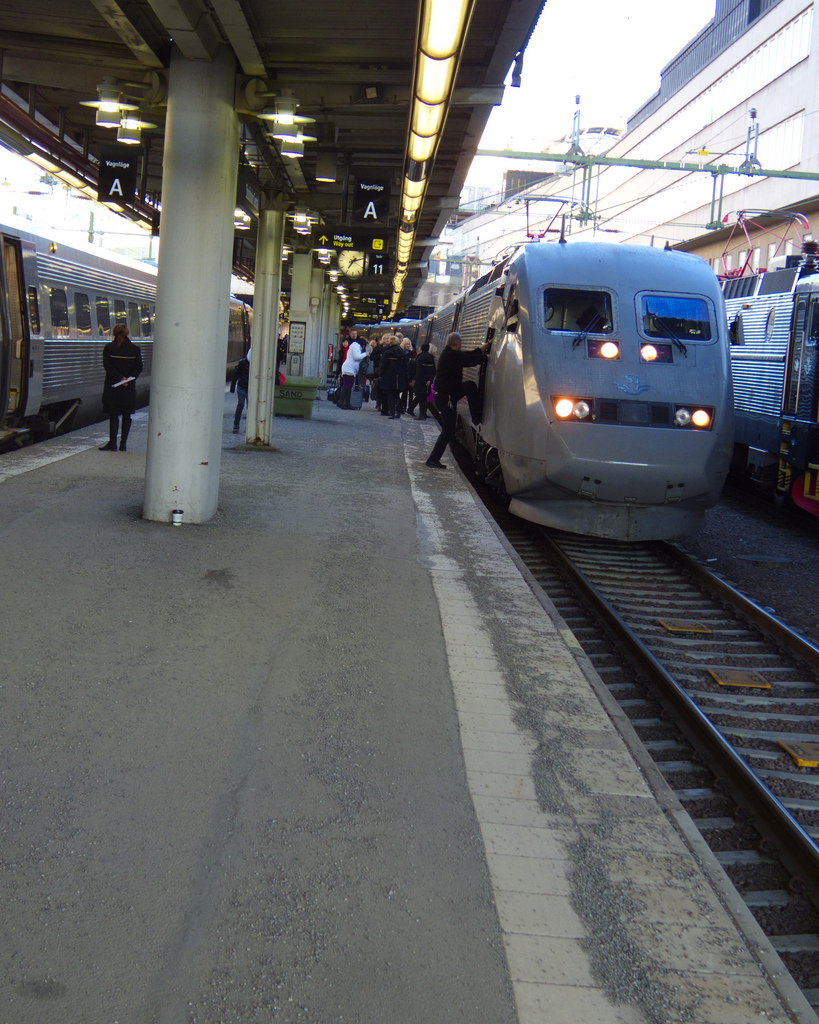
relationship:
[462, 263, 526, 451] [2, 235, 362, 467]
door of train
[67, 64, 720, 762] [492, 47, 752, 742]
picture taken out doors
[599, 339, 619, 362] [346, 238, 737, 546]
headlight on train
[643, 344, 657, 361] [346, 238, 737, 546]
headlight on train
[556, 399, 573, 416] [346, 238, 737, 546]
headlight on train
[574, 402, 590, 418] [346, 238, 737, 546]
headlight on train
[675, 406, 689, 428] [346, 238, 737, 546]
headlight on train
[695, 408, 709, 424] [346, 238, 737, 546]
headlight on train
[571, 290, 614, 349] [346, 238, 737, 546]
windshield wiper on train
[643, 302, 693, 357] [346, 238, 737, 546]
windshield wiper on train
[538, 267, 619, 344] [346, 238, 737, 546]
window on train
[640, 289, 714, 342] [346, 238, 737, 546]
window on train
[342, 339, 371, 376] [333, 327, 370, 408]
sweater on passenger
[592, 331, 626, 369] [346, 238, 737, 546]
headlight on train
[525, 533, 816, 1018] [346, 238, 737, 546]
tracks in front of train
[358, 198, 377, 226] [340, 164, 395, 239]
letter on sign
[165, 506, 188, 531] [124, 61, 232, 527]
cup next to column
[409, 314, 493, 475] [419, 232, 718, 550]
conductor boarding train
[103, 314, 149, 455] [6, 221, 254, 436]
person next to train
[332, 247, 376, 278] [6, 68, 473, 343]
clock hanging from ceiling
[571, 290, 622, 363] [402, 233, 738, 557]
windshield wiper on train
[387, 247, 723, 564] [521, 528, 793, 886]
train on tracks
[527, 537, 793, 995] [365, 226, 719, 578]
tracks in front of train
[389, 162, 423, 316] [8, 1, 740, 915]
light on platform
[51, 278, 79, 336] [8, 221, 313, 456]
window on train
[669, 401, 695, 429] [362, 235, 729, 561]
headlight on train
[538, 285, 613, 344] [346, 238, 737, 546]
window on train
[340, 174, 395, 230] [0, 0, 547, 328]
sign on ceiling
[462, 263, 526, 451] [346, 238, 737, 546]
door on train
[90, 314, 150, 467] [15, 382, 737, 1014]
person in platform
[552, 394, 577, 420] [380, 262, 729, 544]
headlight on train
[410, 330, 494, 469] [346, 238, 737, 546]
conductor boarding train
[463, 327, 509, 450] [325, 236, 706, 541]
door on train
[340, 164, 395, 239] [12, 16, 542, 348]
sign hanging from ceiling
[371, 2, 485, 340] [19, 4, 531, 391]
light on ceiling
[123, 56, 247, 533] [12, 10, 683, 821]
column on platform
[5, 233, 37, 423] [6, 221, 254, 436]
door on train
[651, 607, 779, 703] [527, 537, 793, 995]
blocks on tracks